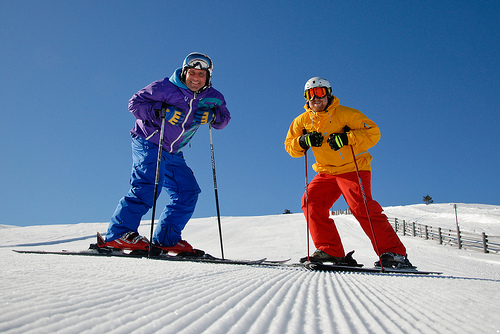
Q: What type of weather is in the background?
A: It is clear.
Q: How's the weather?
A: It is clear.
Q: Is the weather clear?
A: Yes, it is clear.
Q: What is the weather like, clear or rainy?
A: It is clear.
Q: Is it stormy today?
A: No, it is clear.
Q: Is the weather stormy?
A: No, it is clear.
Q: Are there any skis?
A: Yes, there are skis.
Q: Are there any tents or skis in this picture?
A: Yes, there are skis.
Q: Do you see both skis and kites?
A: No, there are skis but no kites.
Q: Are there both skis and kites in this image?
A: No, there are skis but no kites.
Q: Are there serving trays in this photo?
A: No, there are no serving trays.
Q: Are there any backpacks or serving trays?
A: No, there are no serving trays or backpacks.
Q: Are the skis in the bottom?
A: Yes, the skis are in the bottom of the image.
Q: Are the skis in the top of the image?
A: No, the skis are in the bottom of the image.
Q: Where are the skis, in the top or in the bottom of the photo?
A: The skis are in the bottom of the image.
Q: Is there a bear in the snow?
A: No, there are skis in the snow.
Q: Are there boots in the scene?
A: Yes, there are boots.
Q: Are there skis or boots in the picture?
A: Yes, there are boots.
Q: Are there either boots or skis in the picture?
A: Yes, there are boots.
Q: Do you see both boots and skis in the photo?
A: Yes, there are both boots and skis.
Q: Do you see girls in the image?
A: No, there are no girls.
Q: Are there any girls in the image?
A: No, there are no girls.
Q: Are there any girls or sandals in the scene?
A: No, there are no girls or sandals.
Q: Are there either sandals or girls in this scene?
A: No, there are no girls or sandals.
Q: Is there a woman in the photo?
A: No, there are no women.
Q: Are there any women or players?
A: No, there are no women or players.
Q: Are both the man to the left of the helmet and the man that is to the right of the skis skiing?
A: Yes, both the man and the man are skiing.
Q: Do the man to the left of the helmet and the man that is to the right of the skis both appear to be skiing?
A: Yes, both the man and the man are skiing.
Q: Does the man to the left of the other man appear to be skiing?
A: Yes, the man is skiing.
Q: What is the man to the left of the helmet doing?
A: The man is skiing.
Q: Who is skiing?
A: The man is skiing.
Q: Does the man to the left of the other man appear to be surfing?
A: No, the man is skiing.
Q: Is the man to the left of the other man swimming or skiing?
A: The man is skiing.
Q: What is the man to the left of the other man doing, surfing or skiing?
A: The man is skiing.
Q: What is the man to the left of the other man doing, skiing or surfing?
A: The man is skiing.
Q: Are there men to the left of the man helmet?
A: Yes, there is a man to the left of the helmet.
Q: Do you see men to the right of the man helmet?
A: No, the man is to the left of the helmet.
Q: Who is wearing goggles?
A: The man is wearing goggles.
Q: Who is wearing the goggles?
A: The man is wearing goggles.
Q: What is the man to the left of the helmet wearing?
A: The man is wearing goggles.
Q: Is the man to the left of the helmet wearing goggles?
A: Yes, the man is wearing goggles.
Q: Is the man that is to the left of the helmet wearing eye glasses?
A: No, the man is wearing goggles.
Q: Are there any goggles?
A: Yes, there are goggles.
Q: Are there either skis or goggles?
A: Yes, there are goggles.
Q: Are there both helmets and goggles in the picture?
A: Yes, there are both goggles and a helmet.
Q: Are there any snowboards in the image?
A: No, there are no snowboards.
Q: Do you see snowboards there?
A: No, there are no snowboards.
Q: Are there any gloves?
A: Yes, there are gloves.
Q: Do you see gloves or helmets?
A: Yes, there are gloves.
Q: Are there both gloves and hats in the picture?
A: No, there are gloves but no hats.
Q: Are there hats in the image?
A: No, there are no hats.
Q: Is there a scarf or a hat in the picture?
A: No, there are no hats or scarves.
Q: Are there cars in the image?
A: No, there are no cars.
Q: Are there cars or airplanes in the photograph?
A: No, there are no cars or airplanes.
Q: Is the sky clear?
A: Yes, the sky is clear.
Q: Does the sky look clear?
A: Yes, the sky is clear.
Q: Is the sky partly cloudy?
A: No, the sky is clear.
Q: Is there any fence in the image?
A: Yes, there is a fence.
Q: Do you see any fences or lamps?
A: Yes, there is a fence.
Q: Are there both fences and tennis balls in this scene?
A: No, there is a fence but no tennis balls.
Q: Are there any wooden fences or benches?
A: Yes, there is a wood fence.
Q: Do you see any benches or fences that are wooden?
A: Yes, the fence is wooden.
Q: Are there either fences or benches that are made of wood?
A: Yes, the fence is made of wood.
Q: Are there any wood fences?
A: Yes, there is a wood fence.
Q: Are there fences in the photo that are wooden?
A: Yes, there is a fence that is wooden.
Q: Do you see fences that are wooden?
A: Yes, there is a fence that is wooden.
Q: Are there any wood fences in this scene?
A: Yes, there is a fence that is made of wood.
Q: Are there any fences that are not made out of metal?
A: Yes, there is a fence that is made of wood.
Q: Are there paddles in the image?
A: No, there are no paddles.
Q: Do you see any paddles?
A: No, there are no paddles.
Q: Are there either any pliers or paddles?
A: No, there are no paddles or pliers.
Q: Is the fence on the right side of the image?
A: Yes, the fence is on the right of the image.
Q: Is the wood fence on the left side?
A: No, the fence is on the right of the image.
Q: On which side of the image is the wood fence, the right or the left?
A: The fence is on the right of the image.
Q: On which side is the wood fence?
A: The fence is on the right of the image.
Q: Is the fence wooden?
A: Yes, the fence is wooden.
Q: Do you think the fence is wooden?
A: Yes, the fence is wooden.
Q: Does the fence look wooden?
A: Yes, the fence is wooden.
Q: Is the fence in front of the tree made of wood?
A: Yes, the fence is made of wood.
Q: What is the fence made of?
A: The fence is made of wood.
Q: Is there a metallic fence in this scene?
A: No, there is a fence but it is wooden.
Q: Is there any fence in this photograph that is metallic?
A: No, there is a fence but it is wooden.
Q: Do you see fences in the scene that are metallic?
A: No, there is a fence but it is wooden.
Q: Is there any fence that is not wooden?
A: No, there is a fence but it is wooden.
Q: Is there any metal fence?
A: No, there is a fence but it is made of wood.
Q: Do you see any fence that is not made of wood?
A: No, there is a fence but it is made of wood.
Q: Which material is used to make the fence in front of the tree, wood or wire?
A: The fence is made of wood.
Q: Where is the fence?
A: The fence is on the snow.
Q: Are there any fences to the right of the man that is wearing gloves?
A: Yes, there is a fence to the right of the man.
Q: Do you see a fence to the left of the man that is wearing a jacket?
A: No, the fence is to the right of the man.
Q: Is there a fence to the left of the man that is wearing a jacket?
A: No, the fence is to the right of the man.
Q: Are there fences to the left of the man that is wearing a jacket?
A: No, the fence is to the right of the man.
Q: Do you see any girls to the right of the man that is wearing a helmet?
A: No, there is a fence to the right of the man.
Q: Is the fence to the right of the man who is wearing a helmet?
A: Yes, the fence is to the right of the man.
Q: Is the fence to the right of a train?
A: No, the fence is to the right of the man.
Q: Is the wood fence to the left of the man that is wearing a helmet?
A: No, the fence is to the right of the man.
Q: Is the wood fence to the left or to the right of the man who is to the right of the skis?
A: The fence is to the right of the man.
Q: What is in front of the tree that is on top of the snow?
A: The fence is in front of the tree.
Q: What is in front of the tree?
A: The fence is in front of the tree.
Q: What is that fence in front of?
A: The fence is in front of the tree.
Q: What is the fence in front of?
A: The fence is in front of the tree.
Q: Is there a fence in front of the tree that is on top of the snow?
A: Yes, there is a fence in front of the tree.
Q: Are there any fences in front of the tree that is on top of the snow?
A: Yes, there is a fence in front of the tree.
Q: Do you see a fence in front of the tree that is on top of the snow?
A: Yes, there is a fence in front of the tree.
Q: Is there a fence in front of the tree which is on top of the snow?
A: Yes, there is a fence in front of the tree.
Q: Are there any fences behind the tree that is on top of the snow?
A: No, the fence is in front of the tree.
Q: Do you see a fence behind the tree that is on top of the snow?
A: No, the fence is in front of the tree.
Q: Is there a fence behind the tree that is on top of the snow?
A: No, the fence is in front of the tree.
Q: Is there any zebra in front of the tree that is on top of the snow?
A: No, there is a fence in front of the tree.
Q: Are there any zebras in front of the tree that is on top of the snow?
A: No, there is a fence in front of the tree.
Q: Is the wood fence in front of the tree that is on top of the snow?
A: Yes, the fence is in front of the tree.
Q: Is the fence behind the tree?
A: No, the fence is in front of the tree.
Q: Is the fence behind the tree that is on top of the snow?
A: No, the fence is in front of the tree.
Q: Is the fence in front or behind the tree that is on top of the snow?
A: The fence is in front of the tree.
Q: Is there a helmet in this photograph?
A: Yes, there is a helmet.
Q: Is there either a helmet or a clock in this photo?
A: Yes, there is a helmet.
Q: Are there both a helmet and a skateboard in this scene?
A: No, there is a helmet but no skateboards.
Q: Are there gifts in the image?
A: No, there are no gifts.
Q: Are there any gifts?
A: No, there are no gifts.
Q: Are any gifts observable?
A: No, there are no gifts.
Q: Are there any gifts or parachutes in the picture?
A: No, there are no gifts or parachutes.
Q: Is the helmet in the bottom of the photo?
A: No, the helmet is in the top of the image.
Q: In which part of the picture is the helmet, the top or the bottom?
A: The helmet is in the top of the image.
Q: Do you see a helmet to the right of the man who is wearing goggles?
A: Yes, there is a helmet to the right of the man.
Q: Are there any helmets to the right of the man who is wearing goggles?
A: Yes, there is a helmet to the right of the man.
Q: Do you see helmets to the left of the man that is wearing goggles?
A: No, the helmet is to the right of the man.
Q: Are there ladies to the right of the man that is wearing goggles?
A: No, there is a helmet to the right of the man.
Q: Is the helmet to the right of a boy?
A: No, the helmet is to the right of a man.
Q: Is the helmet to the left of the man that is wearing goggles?
A: No, the helmet is to the right of the man.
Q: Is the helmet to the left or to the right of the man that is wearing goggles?
A: The helmet is to the right of the man.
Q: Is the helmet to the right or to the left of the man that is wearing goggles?
A: The helmet is to the right of the man.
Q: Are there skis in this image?
A: Yes, there are skis.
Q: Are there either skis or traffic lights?
A: Yes, there are skis.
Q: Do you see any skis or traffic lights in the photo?
A: Yes, there are skis.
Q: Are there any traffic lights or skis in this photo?
A: Yes, there are skis.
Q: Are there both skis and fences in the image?
A: Yes, there are both skis and a fence.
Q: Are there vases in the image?
A: No, there are no vases.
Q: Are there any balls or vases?
A: No, there are no vases or balls.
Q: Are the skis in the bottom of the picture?
A: Yes, the skis are in the bottom of the image.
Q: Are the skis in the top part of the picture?
A: No, the skis are in the bottom of the image.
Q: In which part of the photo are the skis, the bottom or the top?
A: The skis are in the bottom of the image.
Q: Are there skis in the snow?
A: Yes, there are skis in the snow.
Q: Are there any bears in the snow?
A: No, there are skis in the snow.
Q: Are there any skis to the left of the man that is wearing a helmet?
A: Yes, there are skis to the left of the man.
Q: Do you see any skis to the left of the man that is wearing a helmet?
A: Yes, there are skis to the left of the man.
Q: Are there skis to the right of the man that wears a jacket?
A: No, the skis are to the left of the man.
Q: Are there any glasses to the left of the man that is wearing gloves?
A: No, there are skis to the left of the man.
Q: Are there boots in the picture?
A: Yes, there are boots.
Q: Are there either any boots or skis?
A: Yes, there are boots.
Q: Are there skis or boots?
A: Yes, there are boots.